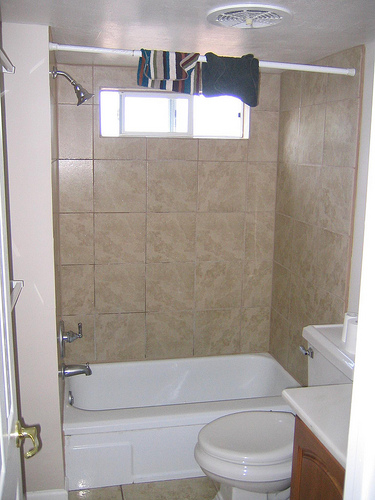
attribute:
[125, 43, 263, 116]
towel — striped, stripes, black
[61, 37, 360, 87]
rod — white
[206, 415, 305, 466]
toilet cover — down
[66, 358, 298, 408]
tub — white, empty, empt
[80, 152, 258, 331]
wall — tiled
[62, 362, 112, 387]
faucet — silver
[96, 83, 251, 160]
window — open